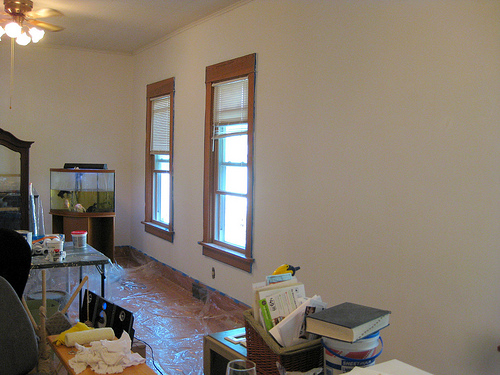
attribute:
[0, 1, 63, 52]
ceiling fan — with light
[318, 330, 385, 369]
white bucket — with blue handle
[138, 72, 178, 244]
window — in a house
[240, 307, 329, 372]
basket — of papers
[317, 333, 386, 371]
bucket — white orange and blue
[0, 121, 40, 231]
framed mirror — large , wood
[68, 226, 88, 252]
small bucket — red and white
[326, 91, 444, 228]
part — of a painted white wall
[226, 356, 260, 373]
part — of a glass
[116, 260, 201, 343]
floor wrap — clear plastic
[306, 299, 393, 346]
large/gray book — on the bucket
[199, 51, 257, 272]
first window — in the room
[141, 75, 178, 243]
second window — in the room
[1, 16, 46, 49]
four lights — on the fan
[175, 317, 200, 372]
small patch — of the waxed floor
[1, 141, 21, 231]
mirror — in the room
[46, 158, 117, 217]
large/fish tank — in the house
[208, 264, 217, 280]
outlet plug — hooked on the wall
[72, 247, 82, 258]
small part — of the waxed table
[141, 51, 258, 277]
rectangular windows — wood trimmed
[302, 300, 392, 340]
one/thick book — with dark cover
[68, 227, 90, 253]
plastic container — little, cylindrical, with red lid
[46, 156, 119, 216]
one/fish tank — with green water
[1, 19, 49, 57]
light — one, illuminated, ceiling fan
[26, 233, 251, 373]
cloth — clear, plastic, painting, drop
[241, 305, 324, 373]
basket — woven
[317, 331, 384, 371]
tub — little, plastic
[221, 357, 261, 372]
top — rounded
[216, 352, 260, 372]
glass — clear